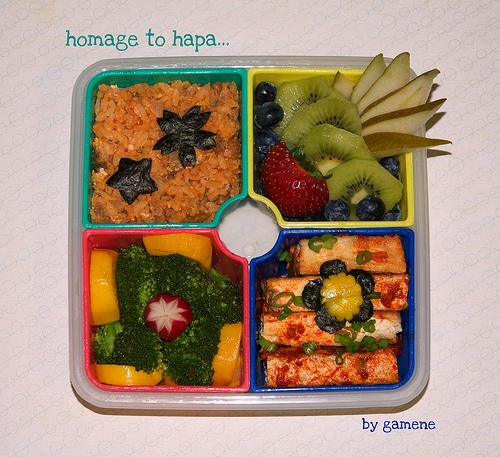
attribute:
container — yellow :
[239, 46, 424, 243]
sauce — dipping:
[222, 200, 274, 257]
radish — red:
[144, 290, 191, 342]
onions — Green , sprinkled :
[377, 337, 387, 347]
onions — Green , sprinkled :
[334, 355, 344, 364]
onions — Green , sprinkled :
[303, 340, 315, 352]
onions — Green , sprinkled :
[258, 336, 276, 351]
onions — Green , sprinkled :
[347, 340, 360, 352]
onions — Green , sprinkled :
[363, 318, 375, 332]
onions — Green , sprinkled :
[355, 247, 371, 263]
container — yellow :
[71, 55, 431, 415]